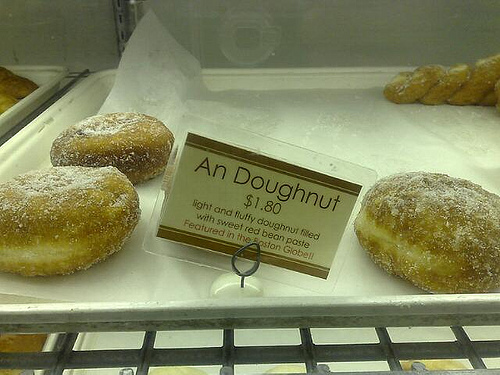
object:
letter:
[264, 178, 279, 194]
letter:
[277, 182, 293, 202]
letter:
[292, 181, 306, 203]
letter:
[305, 189, 320, 207]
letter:
[332, 194, 340, 212]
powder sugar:
[3, 170, 42, 201]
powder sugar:
[34, 170, 69, 189]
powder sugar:
[12, 182, 42, 210]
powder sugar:
[68, 200, 91, 229]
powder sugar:
[68, 174, 101, 201]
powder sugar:
[87, 121, 134, 146]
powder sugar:
[108, 119, 148, 140]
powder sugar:
[385, 194, 467, 213]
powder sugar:
[449, 217, 483, 248]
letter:
[192, 155, 213, 177]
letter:
[212, 162, 227, 179]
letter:
[233, 165, 251, 185]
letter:
[250, 175, 265, 190]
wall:
[2, 4, 499, 77]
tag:
[150, 123, 366, 283]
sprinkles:
[1, 160, 132, 221]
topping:
[2, 155, 118, 222]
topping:
[60, 106, 140, 152]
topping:
[379, 166, 496, 259]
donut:
[352, 170, 500, 295]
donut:
[2, 153, 154, 293]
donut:
[48, 109, 177, 186]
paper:
[0, 55, 500, 303]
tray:
[1, 60, 499, 328]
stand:
[2, 293, 500, 373]